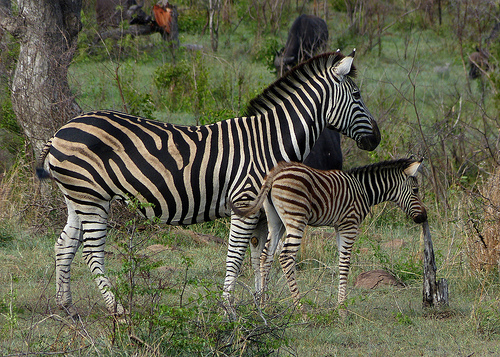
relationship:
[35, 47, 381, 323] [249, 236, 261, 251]
zebra has a patch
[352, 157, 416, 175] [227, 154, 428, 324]
mane on zebra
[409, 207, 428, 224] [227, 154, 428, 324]
mouth on zebra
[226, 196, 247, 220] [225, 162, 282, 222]
hair on tail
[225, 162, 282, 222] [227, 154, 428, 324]
tail on zebra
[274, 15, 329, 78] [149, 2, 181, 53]
buffalo near trunk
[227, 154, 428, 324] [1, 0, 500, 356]
zebra in forrest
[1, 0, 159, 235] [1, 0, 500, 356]
tree in forrest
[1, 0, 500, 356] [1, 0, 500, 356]
greenery in forrest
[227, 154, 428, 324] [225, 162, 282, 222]
zebra has a tail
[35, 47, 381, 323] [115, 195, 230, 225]
zebra has a stomach